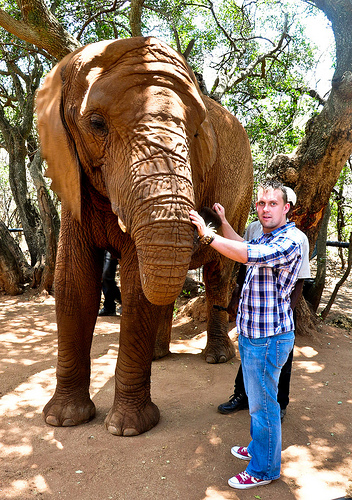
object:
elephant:
[30, 28, 254, 438]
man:
[187, 180, 311, 490]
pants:
[236, 327, 296, 480]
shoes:
[226, 445, 275, 488]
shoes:
[217, 395, 286, 424]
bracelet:
[197, 228, 216, 245]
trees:
[0, 3, 60, 306]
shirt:
[235, 222, 309, 341]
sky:
[0, 0, 352, 143]